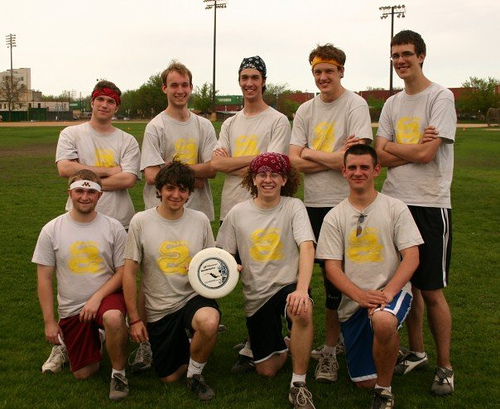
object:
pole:
[212, 0, 217, 112]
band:
[238, 55, 267, 79]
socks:
[186, 357, 208, 378]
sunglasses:
[355, 212, 367, 237]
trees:
[114, 70, 220, 120]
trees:
[455, 75, 500, 123]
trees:
[0, 75, 29, 121]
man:
[373, 29, 457, 396]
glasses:
[389, 53, 418, 61]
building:
[0, 67, 74, 123]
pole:
[10, 33, 15, 108]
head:
[390, 29, 426, 80]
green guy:
[210, 55, 292, 350]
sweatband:
[65, 179, 103, 212]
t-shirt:
[31, 210, 128, 319]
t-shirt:
[122, 205, 217, 323]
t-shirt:
[315, 190, 426, 322]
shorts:
[338, 289, 414, 383]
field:
[0, 126, 500, 409]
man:
[55, 80, 143, 232]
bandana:
[249, 151, 292, 175]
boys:
[313, 143, 425, 409]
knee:
[289, 299, 312, 327]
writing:
[248, 226, 286, 262]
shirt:
[216, 195, 318, 318]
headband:
[311, 55, 345, 71]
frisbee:
[188, 247, 240, 300]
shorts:
[57, 292, 127, 371]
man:
[31, 169, 130, 401]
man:
[121, 152, 242, 400]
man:
[215, 151, 319, 409]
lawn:
[0, 121, 500, 409]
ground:
[0, 121, 61, 215]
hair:
[239, 162, 304, 197]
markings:
[197, 251, 229, 290]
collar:
[347, 191, 380, 216]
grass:
[2, 119, 498, 406]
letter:
[82, 182, 91, 187]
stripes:
[392, 290, 413, 332]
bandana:
[238, 55, 267, 78]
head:
[238, 55, 267, 99]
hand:
[286, 290, 309, 315]